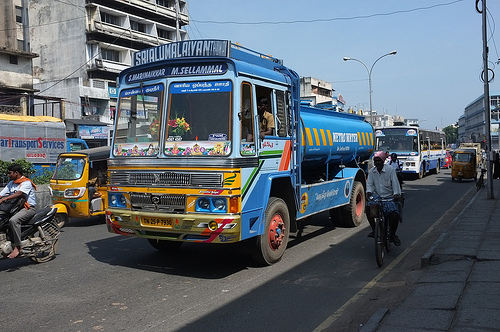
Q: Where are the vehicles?
A: On the road.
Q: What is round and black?
A: Tires.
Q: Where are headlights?
A: On front of the truck.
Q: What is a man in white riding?
A: Bicycle.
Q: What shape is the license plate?
A: Rectangular.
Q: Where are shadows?
A: On the ground.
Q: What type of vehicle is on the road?
A: A truck.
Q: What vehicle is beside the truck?
A: A motorcycle.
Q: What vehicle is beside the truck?
A: A bicycle.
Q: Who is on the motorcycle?
A: A man is on the motorcycle.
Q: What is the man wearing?
A: An orange scarf.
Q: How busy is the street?
A: The street is crowded.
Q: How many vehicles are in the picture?
A: Four.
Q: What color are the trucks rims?
A: Red.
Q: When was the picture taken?
A: During the day.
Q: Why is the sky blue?
A: The sun is shining.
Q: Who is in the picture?
A: Bike riders and a truck driver.